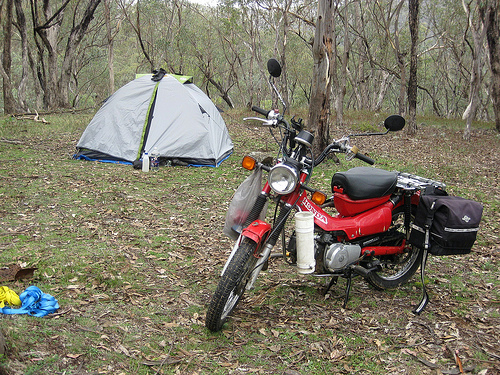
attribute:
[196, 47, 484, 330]
motorcycle — red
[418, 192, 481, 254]
black bag — large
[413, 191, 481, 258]
saddlebag — black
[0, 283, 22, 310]
item — yellow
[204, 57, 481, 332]
scooter — black, red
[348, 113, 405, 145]
mirror — round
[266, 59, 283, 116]
mirror — round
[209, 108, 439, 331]
scooter — red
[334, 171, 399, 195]
seat — black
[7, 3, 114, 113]
trees — dead, dying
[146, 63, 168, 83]
gloves — motorcycle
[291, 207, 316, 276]
tube — large, white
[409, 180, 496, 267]
bag — black and white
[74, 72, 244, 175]
tent — camping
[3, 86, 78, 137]
branches — tree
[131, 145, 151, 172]
bottle — plastic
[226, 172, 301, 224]
bag — plastic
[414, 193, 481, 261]
bag — black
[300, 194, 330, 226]
logo — Honda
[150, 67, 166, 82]
cloth — black